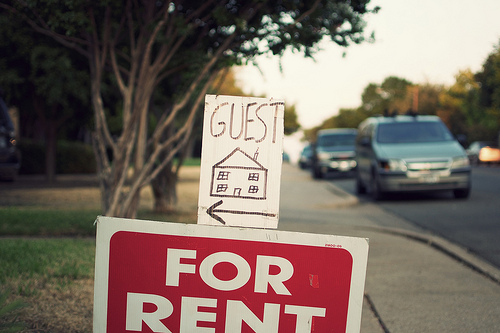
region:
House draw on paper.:
[207, 141, 272, 203]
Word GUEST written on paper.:
[207, 102, 279, 153]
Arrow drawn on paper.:
[208, 195, 292, 235]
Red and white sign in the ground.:
[92, 216, 360, 327]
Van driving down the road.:
[347, 99, 488, 196]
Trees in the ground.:
[57, 6, 197, 227]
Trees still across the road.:
[420, 51, 492, 152]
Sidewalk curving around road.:
[360, 208, 484, 303]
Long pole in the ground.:
[34, 65, 71, 185]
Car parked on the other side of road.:
[470, 133, 497, 171]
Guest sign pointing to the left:
[199, 94, 282, 230]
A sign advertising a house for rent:
[92, 224, 379, 331]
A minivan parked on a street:
[354, 117, 470, 200]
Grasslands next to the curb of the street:
[2, 235, 94, 330]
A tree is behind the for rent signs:
[2, 2, 201, 211]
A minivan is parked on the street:
[312, 130, 354, 178]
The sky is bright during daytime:
[389, 2, 489, 52]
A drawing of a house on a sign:
[207, 147, 270, 200]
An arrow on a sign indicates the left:
[200, 200, 281, 227]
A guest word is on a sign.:
[211, 100, 281, 145]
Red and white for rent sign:
[90, 214, 372, 331]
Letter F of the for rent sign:
[157, 242, 198, 289]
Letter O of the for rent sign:
[196, 248, 251, 294]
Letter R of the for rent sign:
[253, 249, 293, 300]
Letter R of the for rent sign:
[121, 287, 173, 331]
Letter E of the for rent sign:
[178, 292, 223, 332]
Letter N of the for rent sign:
[220, 298, 281, 329]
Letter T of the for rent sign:
[281, 301, 323, 329]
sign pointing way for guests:
[180, 87, 287, 233]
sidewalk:
[265, 217, 498, 331]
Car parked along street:
[351, 114, 472, 202]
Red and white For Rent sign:
[85, 214, 365, 331]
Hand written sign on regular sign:
[193, 92, 286, 232]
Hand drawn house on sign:
[206, 144, 271, 201]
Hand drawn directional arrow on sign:
[202, 199, 276, 231]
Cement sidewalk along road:
[281, 162, 493, 332]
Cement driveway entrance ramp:
[280, 203, 419, 235]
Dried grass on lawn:
[11, 278, 96, 329]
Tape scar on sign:
[302, 270, 324, 288]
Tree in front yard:
[6, 3, 365, 220]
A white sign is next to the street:
[167, 52, 336, 314]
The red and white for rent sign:
[45, 185, 492, 317]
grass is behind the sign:
[11, 221, 142, 276]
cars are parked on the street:
[263, 70, 473, 227]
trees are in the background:
[59, 55, 256, 197]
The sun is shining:
[286, 61, 413, 108]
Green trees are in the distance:
[352, 73, 496, 150]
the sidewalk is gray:
[318, 181, 418, 323]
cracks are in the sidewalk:
[315, 176, 472, 331]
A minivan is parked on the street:
[334, 104, 486, 202]